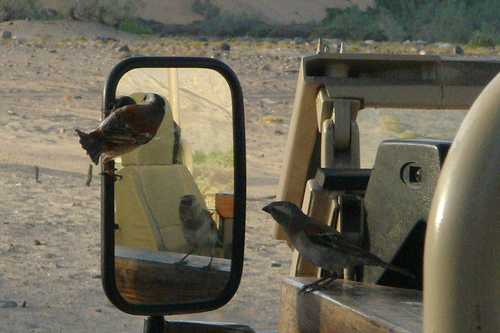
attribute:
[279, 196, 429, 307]
bird — earth tone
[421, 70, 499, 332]
surface — curved, tan, metal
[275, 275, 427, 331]
box — wooden, under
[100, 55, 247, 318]
mirror frame — black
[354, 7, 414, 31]
leaves — green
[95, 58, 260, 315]
mirror — rear view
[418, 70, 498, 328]
rail — gray, metal, curved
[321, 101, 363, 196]
hinge — bending 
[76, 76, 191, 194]
bird — gray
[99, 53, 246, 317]
frame — black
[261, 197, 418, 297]
bird — small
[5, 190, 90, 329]
dirt — behind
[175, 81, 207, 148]
mirror — clean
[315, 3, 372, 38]
tree — tall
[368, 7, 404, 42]
tree — tall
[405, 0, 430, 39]
tree — tall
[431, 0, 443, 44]
tree — tall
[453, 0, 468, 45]
tree — tall